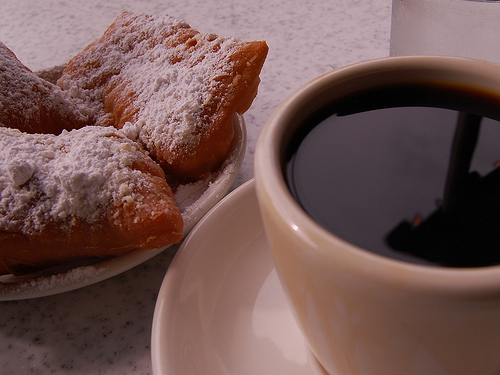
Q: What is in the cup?
A: Coffee.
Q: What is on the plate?
A: Pastry.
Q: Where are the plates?
A: On the table.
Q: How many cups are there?
A: One.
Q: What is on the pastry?
A: Sugar.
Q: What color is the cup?
A: White.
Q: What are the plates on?
A: A table.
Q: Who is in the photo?
A: No one.